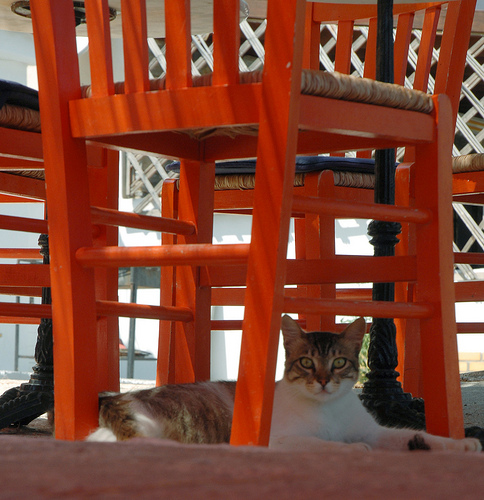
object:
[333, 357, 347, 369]
eyes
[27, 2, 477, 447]
chair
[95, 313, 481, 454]
cat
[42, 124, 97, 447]
legs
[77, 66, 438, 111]
cushion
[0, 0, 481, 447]
table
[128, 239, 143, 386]
post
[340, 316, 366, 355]
ear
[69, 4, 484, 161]
fence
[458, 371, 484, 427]
ground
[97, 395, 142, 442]
tail